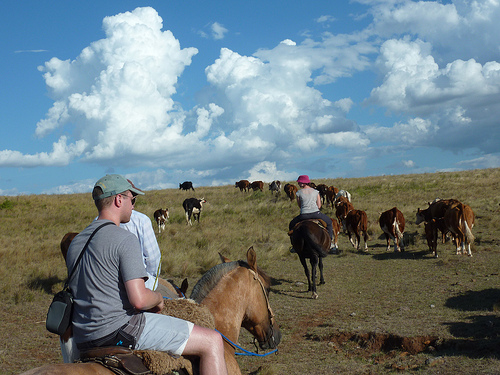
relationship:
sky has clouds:
[7, 0, 499, 167] [31, 0, 456, 153]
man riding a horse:
[48, 173, 229, 375] [19, 245, 284, 373]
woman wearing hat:
[287, 175, 335, 251] [296, 174, 311, 184]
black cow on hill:
[178, 179, 195, 189] [18, 168, 478, 205]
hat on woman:
[294, 174, 310, 184] [289, 175, 332, 255]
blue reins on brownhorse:
[211, 320, 281, 361] [23, 244, 286, 374]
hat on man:
[88, 171, 148, 196] [48, 173, 229, 375]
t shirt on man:
[59, 233, 163, 350] [48, 173, 229, 375]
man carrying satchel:
[50, 174, 255, 349] [40, 220, 120, 340]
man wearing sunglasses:
[48, 173, 229, 375] [117, 195, 144, 209]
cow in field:
[292, 209, 339, 301] [4, 173, 497, 373]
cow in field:
[349, 206, 375, 248] [4, 173, 497, 373]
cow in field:
[372, 193, 415, 255] [4, 173, 497, 373]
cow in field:
[426, 196, 481, 258] [4, 173, 497, 373]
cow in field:
[184, 191, 211, 216] [4, 173, 497, 373]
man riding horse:
[48, 173, 229, 375] [193, 230, 305, 329]